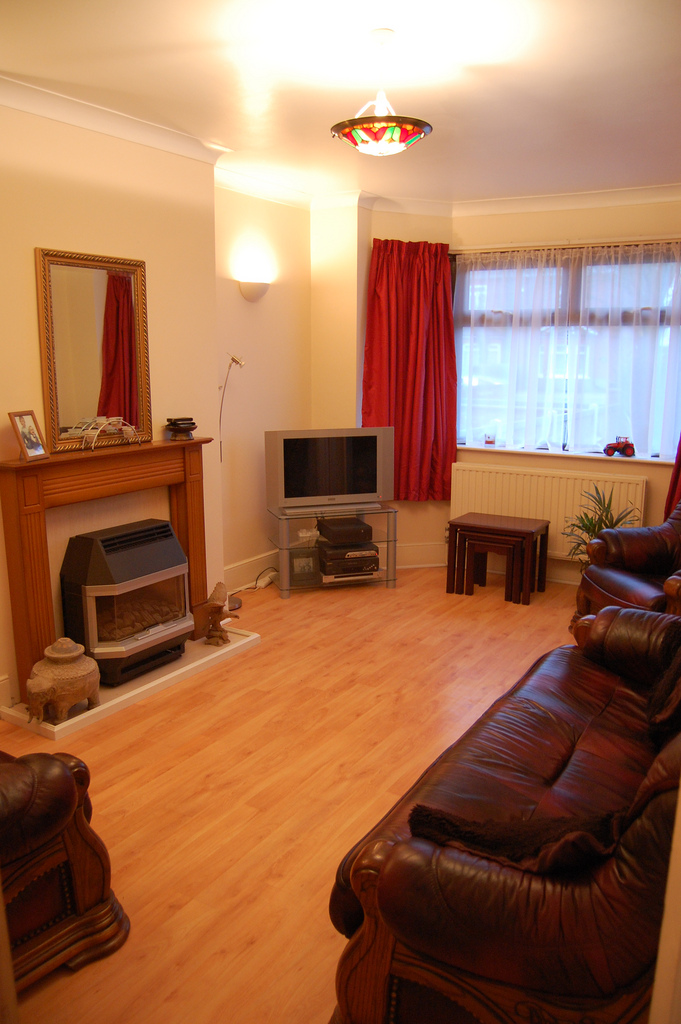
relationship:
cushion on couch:
[458, 768, 601, 889] [396, 581, 680, 986]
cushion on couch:
[585, 503, 676, 570] [567, 494, 675, 636]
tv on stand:
[260, 424, 398, 509] [268, 499, 407, 598]